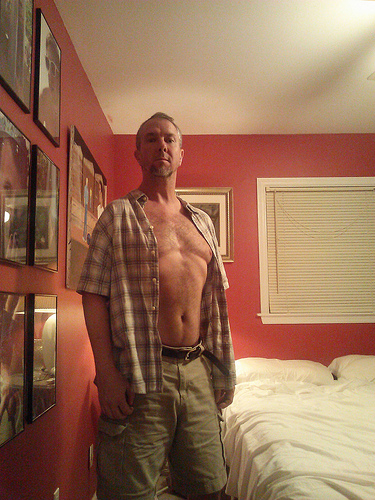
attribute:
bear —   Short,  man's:
[131, 153, 201, 183]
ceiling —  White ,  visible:
[49, 0, 374, 138]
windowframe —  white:
[260, 153, 373, 331]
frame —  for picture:
[68, 131, 104, 282]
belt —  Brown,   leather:
[165, 347, 204, 361]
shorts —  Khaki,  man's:
[91, 336, 227, 498]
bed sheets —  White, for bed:
[222, 355, 374, 498]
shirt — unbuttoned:
[78, 190, 236, 391]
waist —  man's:
[114, 347, 222, 360]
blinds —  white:
[274, 235, 372, 311]